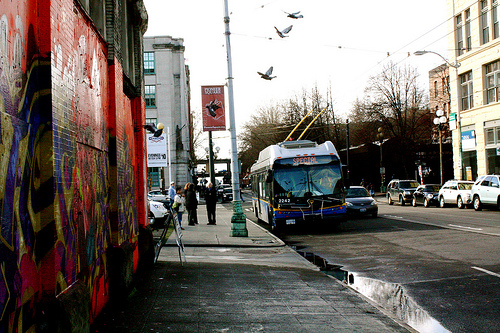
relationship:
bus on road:
[250, 142, 350, 232] [226, 190, 498, 332]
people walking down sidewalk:
[168, 177, 222, 222] [147, 197, 374, 332]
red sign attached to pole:
[202, 84, 225, 134] [223, 1, 246, 234]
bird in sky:
[257, 69, 277, 78] [142, 3, 443, 111]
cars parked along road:
[386, 178, 500, 209] [226, 190, 498, 332]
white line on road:
[471, 263, 500, 276] [226, 190, 498, 332]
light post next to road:
[413, 50, 463, 182] [226, 190, 498, 332]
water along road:
[291, 248, 405, 315] [226, 190, 498, 332]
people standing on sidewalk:
[168, 177, 222, 222] [147, 197, 374, 332]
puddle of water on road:
[291, 248, 405, 315] [226, 190, 498, 332]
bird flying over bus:
[257, 69, 277, 78] [250, 142, 350, 232]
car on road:
[342, 186, 377, 212] [226, 190, 498, 332]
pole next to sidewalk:
[223, 1, 246, 234] [147, 197, 374, 332]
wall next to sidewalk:
[1, 2, 147, 332] [147, 197, 374, 332]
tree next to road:
[325, 118, 445, 175] [226, 190, 498, 332]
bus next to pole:
[250, 142, 350, 232] [223, 1, 246, 234]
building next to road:
[425, 66, 456, 116] [226, 190, 498, 332]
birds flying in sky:
[253, 9, 307, 87] [142, 3, 443, 111]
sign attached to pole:
[202, 84, 225, 134] [223, 1, 246, 234]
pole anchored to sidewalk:
[223, 1, 246, 234] [147, 197, 374, 332]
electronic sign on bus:
[284, 155, 328, 168] [250, 142, 350, 232]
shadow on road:
[331, 216, 424, 231] [226, 190, 498, 332]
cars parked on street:
[386, 178, 500, 209] [226, 190, 498, 332]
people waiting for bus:
[168, 177, 222, 222] [250, 142, 350, 232]